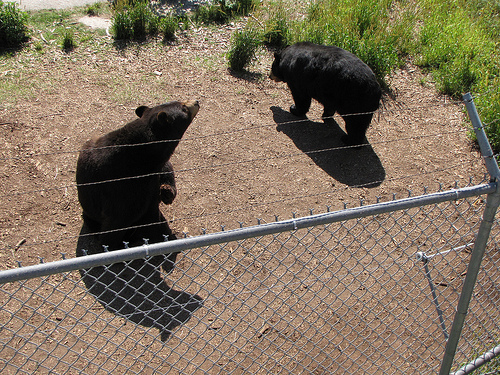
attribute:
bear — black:
[72, 37, 385, 235]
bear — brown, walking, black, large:
[263, 41, 381, 152]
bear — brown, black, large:
[72, 96, 205, 256]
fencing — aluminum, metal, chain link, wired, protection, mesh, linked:
[2, 94, 500, 373]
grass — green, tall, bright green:
[2, 2, 500, 162]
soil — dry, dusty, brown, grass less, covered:
[1, 53, 499, 374]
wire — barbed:
[3, 88, 496, 272]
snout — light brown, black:
[193, 99, 201, 109]